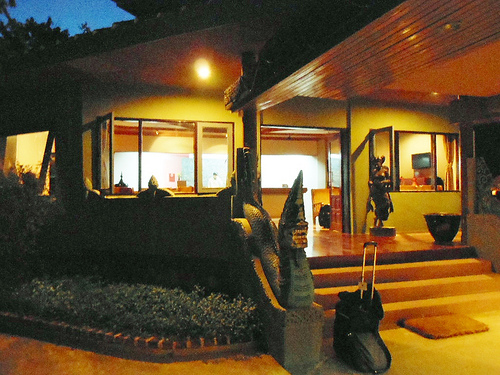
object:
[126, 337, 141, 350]
brick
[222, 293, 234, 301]
flower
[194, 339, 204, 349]
brick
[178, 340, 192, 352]
brick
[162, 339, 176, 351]
brick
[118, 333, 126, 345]
brick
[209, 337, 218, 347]
brick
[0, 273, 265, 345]
flower bed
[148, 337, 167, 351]
brick